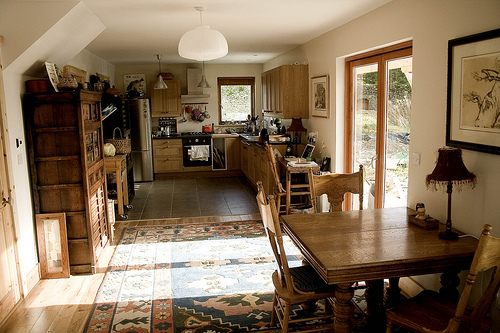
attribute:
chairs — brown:
[308, 167, 369, 219]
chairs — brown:
[247, 183, 350, 331]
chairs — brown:
[402, 233, 498, 324]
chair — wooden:
[247, 177, 352, 329]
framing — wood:
[217, 71, 257, 90]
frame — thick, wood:
[55, 211, 71, 281]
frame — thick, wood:
[443, 42, 459, 140]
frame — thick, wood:
[325, 75, 333, 115]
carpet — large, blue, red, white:
[83, 219, 438, 331]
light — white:
[171, 17, 234, 65]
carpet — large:
[75, 225, 407, 331]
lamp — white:
[173, 14, 229, 64]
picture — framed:
[32, 210, 70, 283]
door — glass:
[315, 39, 471, 238]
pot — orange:
[200, 125, 211, 134]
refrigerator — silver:
[136, 95, 163, 167]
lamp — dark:
[410, 124, 496, 258]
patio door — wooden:
[336, 34, 420, 226]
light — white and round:
[179, 7, 228, 60]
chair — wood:
[254, 179, 344, 331]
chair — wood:
[305, 163, 365, 214]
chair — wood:
[380, 222, 493, 332]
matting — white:
[463, 45, 472, 53]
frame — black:
[444, 27, 493, 47]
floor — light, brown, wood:
[41, 279, 71, 331]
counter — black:
[212, 124, 269, 135]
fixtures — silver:
[184, 50, 239, 62]